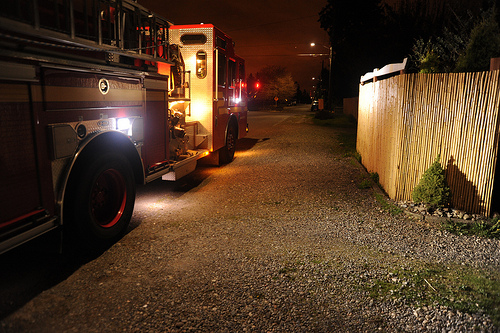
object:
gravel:
[196, 299, 496, 333]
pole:
[315, 78, 332, 120]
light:
[116, 117, 131, 130]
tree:
[411, 154, 452, 213]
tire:
[75, 144, 136, 241]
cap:
[98, 78, 110, 95]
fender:
[52, 130, 148, 220]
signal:
[254, 81, 261, 88]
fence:
[347, 72, 499, 217]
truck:
[0, 0, 248, 268]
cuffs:
[172, 125, 186, 138]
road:
[0, 104, 500, 333]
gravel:
[430, 223, 492, 266]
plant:
[412, 21, 463, 77]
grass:
[451, 271, 493, 294]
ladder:
[2, 2, 176, 65]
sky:
[219, 3, 299, 66]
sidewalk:
[33, 104, 500, 333]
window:
[196, 49, 207, 79]